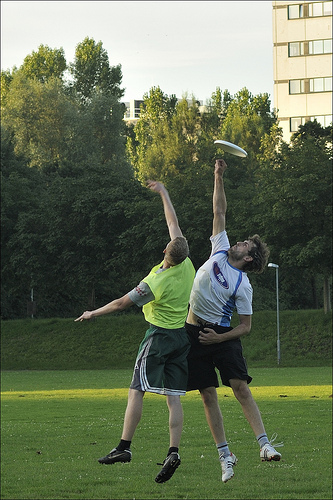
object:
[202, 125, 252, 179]
frisbee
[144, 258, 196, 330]
vest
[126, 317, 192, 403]
shorts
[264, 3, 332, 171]
building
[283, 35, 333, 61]
windows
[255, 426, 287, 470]
shoes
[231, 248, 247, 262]
facial hair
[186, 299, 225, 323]
belly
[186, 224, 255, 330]
shirt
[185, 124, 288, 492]
men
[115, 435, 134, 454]
socks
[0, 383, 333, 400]
light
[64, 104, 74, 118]
leaves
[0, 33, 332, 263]
branches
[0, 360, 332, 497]
field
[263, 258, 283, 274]
lamp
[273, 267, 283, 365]
pole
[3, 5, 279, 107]
sky